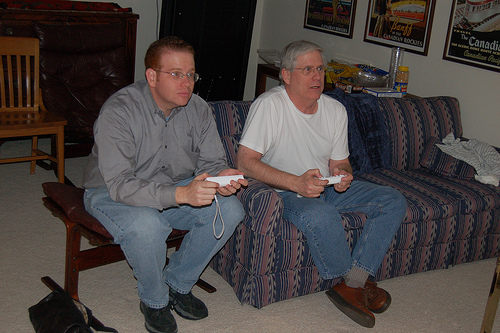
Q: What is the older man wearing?
A: Dark blue jeans.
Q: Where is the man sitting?
A: On a sofa.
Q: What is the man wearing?
A: Grey shirt.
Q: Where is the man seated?
A: On a brown seat.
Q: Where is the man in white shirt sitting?
A: Couch.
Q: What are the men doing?
A: Playing wii.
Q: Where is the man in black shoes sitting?
A: Ottoman.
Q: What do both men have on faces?
A: Glasses.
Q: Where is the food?
A: Table.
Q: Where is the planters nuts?
A: Table.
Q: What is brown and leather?
A: A recliner.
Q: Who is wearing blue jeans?
A: Both men.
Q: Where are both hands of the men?
A: Wii controller.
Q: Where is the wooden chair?
A: Behind ottoman.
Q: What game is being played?
A: Wii.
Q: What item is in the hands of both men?
A: Wii controller.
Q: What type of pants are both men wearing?
A: Jean.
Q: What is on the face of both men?
A: Eyeglasses.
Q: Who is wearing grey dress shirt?
A: The man on the left.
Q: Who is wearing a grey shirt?
A: Man on left.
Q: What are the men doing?
A: Playing game.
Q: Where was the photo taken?
A: Living room.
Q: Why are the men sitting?
A: Playing game.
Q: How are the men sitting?
A: Next to each other.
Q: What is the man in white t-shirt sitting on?
A: Couch.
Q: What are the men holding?
A: Game controls.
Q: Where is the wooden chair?
A: Far left.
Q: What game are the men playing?
A: Wii.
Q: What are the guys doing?
A: Playing.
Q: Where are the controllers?
A: In their hands.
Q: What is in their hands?
A: Controllers.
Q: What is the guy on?
A: Couch.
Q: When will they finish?
A: Soon.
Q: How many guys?
A: 2.